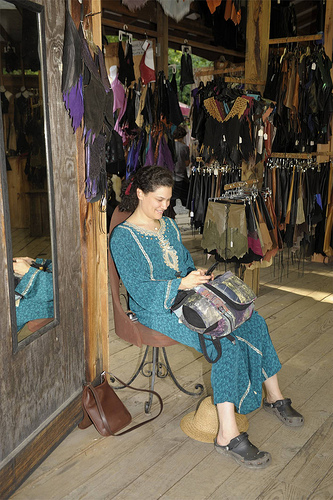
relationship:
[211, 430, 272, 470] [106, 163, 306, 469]
clog of a woman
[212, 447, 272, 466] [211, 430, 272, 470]
dirt on bottom of clog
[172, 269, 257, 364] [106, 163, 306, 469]
handbag of a woman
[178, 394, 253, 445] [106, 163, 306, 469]
hat of woman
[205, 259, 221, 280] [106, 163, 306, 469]
phone of a woman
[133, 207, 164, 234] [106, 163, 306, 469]
necklace of a woman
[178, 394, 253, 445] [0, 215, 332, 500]
hat sitting on floor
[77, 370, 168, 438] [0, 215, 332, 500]
purse on top of floor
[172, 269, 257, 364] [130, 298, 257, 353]
handbag on top of lap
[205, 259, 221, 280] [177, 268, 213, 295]
phone in hand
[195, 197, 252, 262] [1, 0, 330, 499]
skirt inside a store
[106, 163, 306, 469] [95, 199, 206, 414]
woman sitting on chair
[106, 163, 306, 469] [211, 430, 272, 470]
woman wearing clog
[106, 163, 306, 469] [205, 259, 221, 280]
woman holding phone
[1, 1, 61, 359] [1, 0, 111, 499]
mirror hanging on wall